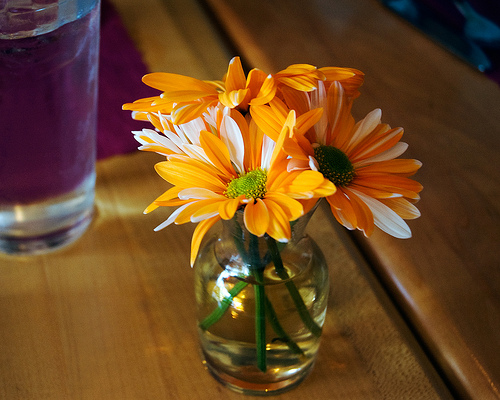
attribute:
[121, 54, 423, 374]
flowers — two colors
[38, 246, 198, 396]
table — wooden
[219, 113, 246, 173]
petal — white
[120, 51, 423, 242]
flowers — colorful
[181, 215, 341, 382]
vase — small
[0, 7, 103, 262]
water glass — full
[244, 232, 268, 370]
stem — green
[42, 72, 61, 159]
liquid — purple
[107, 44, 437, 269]
flowers — colorful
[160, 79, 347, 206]
flowers — orange, white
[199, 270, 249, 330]
stem — green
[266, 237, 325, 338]
stem — green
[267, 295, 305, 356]
stem — green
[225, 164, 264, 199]
middle — green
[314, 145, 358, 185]
middle — green